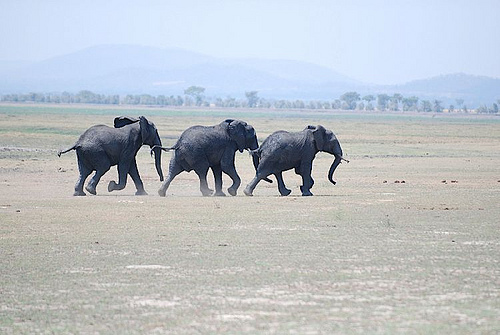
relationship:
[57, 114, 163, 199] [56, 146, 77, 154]
elephant has tail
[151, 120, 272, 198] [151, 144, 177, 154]
elephant has tail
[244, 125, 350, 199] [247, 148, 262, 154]
elephant has tail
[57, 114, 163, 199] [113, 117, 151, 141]
elephant has ears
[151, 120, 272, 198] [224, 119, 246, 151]
elephant has ears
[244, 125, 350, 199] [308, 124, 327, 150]
elephant has ears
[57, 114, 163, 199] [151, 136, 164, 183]
elephant has trunk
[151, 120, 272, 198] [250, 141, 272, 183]
elephant has trunk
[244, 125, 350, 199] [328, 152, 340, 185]
elephant has trunk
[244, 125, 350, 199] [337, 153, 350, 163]
elephant has tusk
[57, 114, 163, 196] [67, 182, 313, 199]
elephant kicking dust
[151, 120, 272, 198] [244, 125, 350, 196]
elephant in elephant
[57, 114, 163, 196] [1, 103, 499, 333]
elephant on grass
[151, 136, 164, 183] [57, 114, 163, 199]
trunk of elephant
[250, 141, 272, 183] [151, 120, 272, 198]
trunk of elephant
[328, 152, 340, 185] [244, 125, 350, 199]
trunk of elephant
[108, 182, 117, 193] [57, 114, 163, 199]
foot of elephant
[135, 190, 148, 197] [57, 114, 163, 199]
foot of elephant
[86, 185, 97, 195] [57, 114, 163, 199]
foot of elephant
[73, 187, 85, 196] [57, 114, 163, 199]
foot of elephant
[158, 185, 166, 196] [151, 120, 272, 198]
foot of elephant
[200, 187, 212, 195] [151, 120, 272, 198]
foot of elephant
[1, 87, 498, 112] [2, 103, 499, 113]
trees on edge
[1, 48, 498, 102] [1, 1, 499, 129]
mountains in distance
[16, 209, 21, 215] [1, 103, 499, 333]
rock on floor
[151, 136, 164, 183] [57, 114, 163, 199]
trunk on elephant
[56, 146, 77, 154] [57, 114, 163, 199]
tail of elephant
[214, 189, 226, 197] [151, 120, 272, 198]
foot of elephant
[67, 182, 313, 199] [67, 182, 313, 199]
dust of dust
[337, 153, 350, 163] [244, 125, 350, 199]
tusk on elephant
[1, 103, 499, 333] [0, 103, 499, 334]
grass on plain